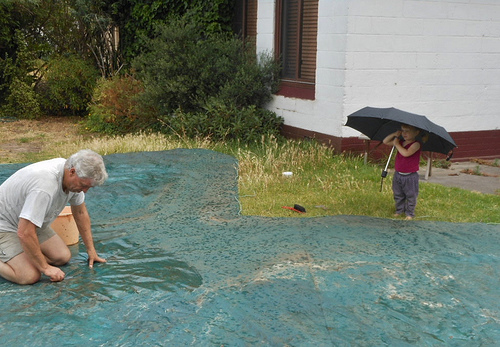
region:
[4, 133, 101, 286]
man on his knees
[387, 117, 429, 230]
little boy in red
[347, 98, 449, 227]
little boy holding the umbrella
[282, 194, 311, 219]
the scrub brush on the ground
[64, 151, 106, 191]
the man's silver hair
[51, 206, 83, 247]
the bucket beside the man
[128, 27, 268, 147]
the bushes beside the house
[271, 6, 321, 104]
the window with closed shutters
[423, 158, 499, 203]
the concrete ground behind the boy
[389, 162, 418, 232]
the little biy's blue pants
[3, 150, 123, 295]
a man kneeling on the ground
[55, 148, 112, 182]
his hair is white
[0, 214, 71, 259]
he is wearing shorts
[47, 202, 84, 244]
a yellow bucket behind the man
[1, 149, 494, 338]
green plastic on the ground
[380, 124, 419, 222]
a child watching the man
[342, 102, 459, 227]
the child is holding an umbrella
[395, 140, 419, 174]
she is wearing a pink shirt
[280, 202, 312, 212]
a brush on the ground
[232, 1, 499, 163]
a house behind the child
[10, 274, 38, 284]
Knee on the ground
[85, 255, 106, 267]
Hand in the ground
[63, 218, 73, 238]
A bucket on the ground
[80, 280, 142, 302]
A wet greenish surface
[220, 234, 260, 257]
Drops of rain on the surface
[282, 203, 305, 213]
A brush on the grass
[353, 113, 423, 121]
An open black umbrella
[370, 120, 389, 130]
The underside of an umbrella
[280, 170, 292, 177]
A white object in the grass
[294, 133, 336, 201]
part of a ground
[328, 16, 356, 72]
edge of a wall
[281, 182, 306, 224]
part of a bruah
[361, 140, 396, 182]
part of a handle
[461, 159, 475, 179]
part of a floor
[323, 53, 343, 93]
edge of a wall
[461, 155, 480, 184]
part of a floor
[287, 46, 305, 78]
part of a window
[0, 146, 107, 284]
An older man in a white shirt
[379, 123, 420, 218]
A young child in a red shirt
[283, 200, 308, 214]
A brush on the ground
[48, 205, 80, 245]
An orange plastic bucket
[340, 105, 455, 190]
A black umbrella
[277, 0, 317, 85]
a window on a house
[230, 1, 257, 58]
A window on a house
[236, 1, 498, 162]
A red and white building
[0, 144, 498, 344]
A large green tarp on the ground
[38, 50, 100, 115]
A small green bush